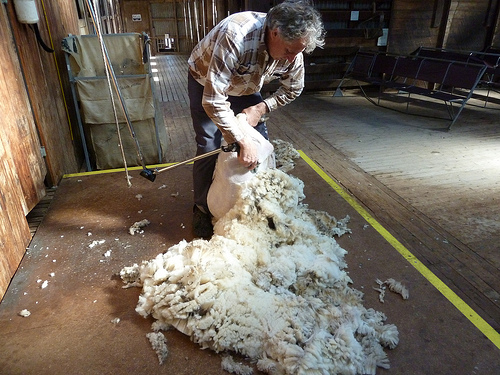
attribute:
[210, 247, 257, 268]
fur — gathered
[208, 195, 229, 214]
sheep — cut, part, shaved, sheered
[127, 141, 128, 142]
bag — brown, white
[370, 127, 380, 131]
floor — old, large, brown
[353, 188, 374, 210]
line — yellow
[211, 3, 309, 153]
man — bending, trmming, shaving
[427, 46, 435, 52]
chairs — set, part, edge, dark, silver, brown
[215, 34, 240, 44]
shirt — checkered, part, plaid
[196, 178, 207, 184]
jeans — blue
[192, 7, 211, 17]
hallway — wooden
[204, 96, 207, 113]
elbow — part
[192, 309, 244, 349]
wool — pile, white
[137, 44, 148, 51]
cloth — tan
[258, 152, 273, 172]
tool — metal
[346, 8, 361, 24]
sign — white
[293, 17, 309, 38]
hair — gray, grey, white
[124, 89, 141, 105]
bin — tan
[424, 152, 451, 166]
sunlight — shining